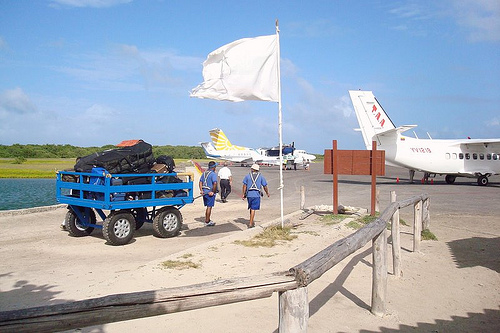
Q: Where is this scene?
A: Beach.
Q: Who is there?
A: Men.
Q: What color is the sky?
A: Blue.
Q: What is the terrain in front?
A: Sand.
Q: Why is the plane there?
A: Transport.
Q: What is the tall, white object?
A: Flag.